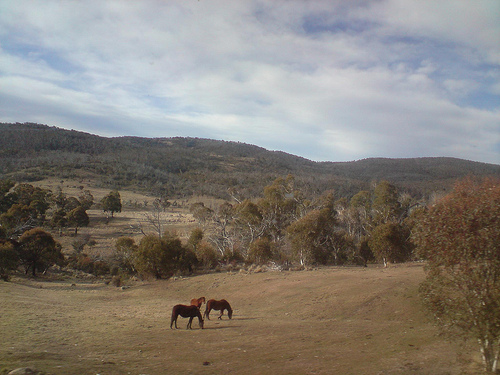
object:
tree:
[98, 187, 124, 219]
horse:
[201, 296, 236, 321]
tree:
[365, 219, 419, 266]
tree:
[0, 238, 22, 285]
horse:
[189, 295, 206, 309]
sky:
[1, 0, 499, 165]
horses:
[169, 303, 204, 330]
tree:
[177, 245, 200, 277]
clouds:
[1, 1, 500, 165]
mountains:
[1, 121, 499, 260]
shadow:
[189, 322, 243, 331]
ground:
[1, 264, 499, 374]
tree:
[63, 204, 92, 238]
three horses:
[168, 292, 235, 330]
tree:
[15, 225, 71, 278]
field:
[1, 170, 499, 374]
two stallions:
[171, 298, 236, 330]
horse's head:
[225, 305, 235, 319]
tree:
[408, 171, 500, 374]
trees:
[192, 205, 214, 231]